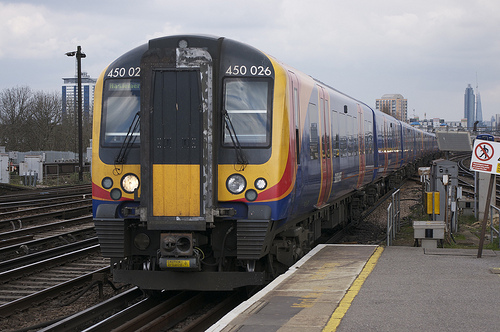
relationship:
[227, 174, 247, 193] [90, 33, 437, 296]
headlight on train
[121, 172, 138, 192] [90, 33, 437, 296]
headlight on train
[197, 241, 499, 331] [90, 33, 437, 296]
platform near train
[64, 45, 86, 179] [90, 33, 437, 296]
electric pole near train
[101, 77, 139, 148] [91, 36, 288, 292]
window on train front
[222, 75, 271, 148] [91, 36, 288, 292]
window on train front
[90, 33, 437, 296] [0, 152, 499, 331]
train on tracks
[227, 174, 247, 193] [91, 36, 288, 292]
headlight on train front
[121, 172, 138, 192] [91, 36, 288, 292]
headlight on train front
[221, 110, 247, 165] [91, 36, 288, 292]
windshield wiper on train front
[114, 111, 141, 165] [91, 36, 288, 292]
windshield wiper on train front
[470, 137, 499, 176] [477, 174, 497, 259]
sign on pole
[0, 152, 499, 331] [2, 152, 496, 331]
tracks on ground